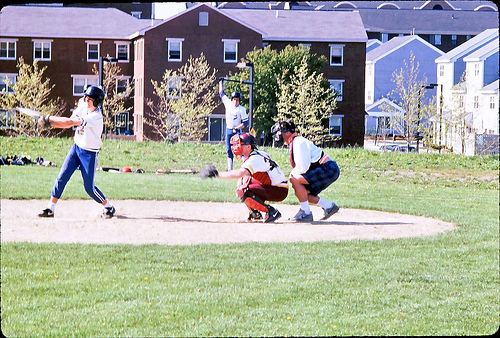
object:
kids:
[205, 129, 290, 222]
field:
[0, 136, 499, 337]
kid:
[39, 86, 115, 218]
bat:
[14, 102, 44, 119]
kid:
[218, 78, 249, 173]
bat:
[218, 76, 256, 84]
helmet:
[84, 85, 105, 105]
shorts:
[301, 160, 339, 196]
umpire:
[271, 121, 340, 223]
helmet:
[239, 132, 257, 147]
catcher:
[204, 132, 289, 225]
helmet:
[278, 121, 297, 133]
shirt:
[73, 97, 103, 150]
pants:
[48, 145, 107, 203]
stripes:
[93, 188, 107, 203]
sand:
[0, 199, 462, 246]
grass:
[0, 165, 498, 335]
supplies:
[157, 169, 169, 174]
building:
[133, 2, 365, 148]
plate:
[60, 212, 99, 222]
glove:
[200, 164, 217, 179]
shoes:
[266, 210, 282, 224]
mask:
[230, 134, 243, 159]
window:
[223, 39, 239, 62]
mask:
[271, 121, 284, 148]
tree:
[390, 50, 425, 152]